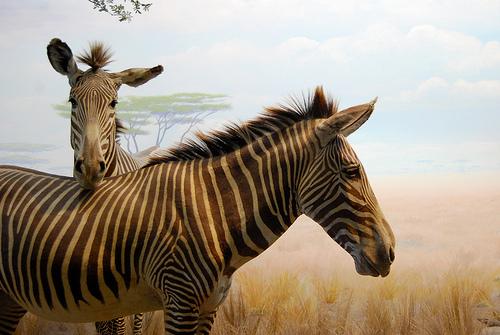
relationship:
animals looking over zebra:
[0, 37, 396, 335] [4, 89, 381, 334]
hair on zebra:
[73, 38, 116, 72] [14, 15, 411, 333]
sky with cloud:
[1, 0, 500, 170] [404, 71, 498, 115]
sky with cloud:
[1, 0, 500, 170] [182, 3, 496, 97]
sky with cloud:
[1, 0, 500, 170] [2, 128, 64, 165]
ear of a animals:
[45, 38, 78, 82] [0, 37, 396, 335]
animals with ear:
[0, 37, 396, 335] [43, 34, 81, 77]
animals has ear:
[0, 37, 396, 335] [44, 40, 82, 81]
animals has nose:
[0, 37, 396, 335] [72, 154, 111, 190]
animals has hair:
[0, 37, 396, 335] [140, 84, 340, 168]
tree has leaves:
[52, 87, 231, 174] [155, 102, 205, 118]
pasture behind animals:
[258, 187, 489, 282] [0, 37, 396, 335]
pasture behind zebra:
[258, 187, 489, 282] [34, 16, 185, 195]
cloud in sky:
[0, 0, 500, 173] [51, 13, 446, 206]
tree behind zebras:
[52, 92, 232, 155] [1, 30, 402, 333]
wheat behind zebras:
[10, 261, 498, 332] [1, 30, 402, 333]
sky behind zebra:
[1, 1, 498, 164] [0, 36, 405, 331]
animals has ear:
[0, 37, 396, 335] [46, 38, 76, 75]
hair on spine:
[164, 111, 328, 153] [173, 118, 338, 153]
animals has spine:
[0, 37, 396, 335] [173, 118, 338, 153]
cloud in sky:
[0, 0, 500, 173] [4, 0, 499, 91]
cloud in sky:
[207, 27, 494, 69] [4, 0, 499, 91]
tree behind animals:
[52, 92, 232, 155] [0, 35, 417, 333]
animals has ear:
[0, 37, 396, 335] [115, 60, 164, 90]